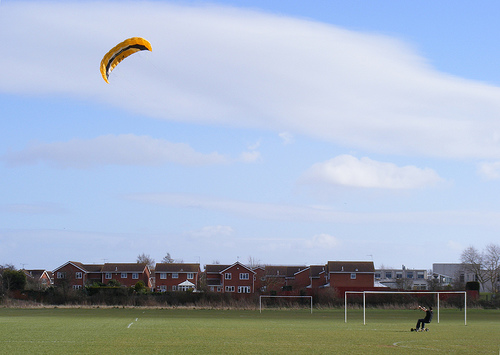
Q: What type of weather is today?
A: It is cloudy.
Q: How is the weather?
A: It is cloudy.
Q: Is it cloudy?
A: Yes, it is cloudy.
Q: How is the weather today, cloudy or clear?
A: It is cloudy.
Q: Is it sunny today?
A: No, it is cloudy.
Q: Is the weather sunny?
A: No, it is cloudy.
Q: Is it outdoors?
A: Yes, it is outdoors.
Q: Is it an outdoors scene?
A: Yes, it is outdoors.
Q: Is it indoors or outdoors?
A: It is outdoors.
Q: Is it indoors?
A: No, it is outdoors.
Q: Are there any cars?
A: No, there are no cars.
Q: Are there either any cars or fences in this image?
A: No, there are no cars or fences.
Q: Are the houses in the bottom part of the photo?
A: Yes, the houses are in the bottom of the image.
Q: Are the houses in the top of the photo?
A: No, the houses are in the bottom of the image.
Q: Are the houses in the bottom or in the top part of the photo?
A: The houses are in the bottom of the image.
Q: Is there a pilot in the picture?
A: No, there are no pilots.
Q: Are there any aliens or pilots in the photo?
A: No, there are no pilots or aliens.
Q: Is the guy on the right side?
A: Yes, the guy is on the right of the image.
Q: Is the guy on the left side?
A: No, the guy is on the right of the image.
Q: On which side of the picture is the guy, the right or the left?
A: The guy is on the right of the image.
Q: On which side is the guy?
A: The guy is on the right of the image.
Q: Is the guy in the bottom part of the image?
A: Yes, the guy is in the bottom of the image.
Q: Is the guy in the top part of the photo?
A: No, the guy is in the bottom of the image.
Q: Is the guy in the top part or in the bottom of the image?
A: The guy is in the bottom of the image.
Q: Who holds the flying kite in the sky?
A: The guy holds the kite.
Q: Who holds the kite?
A: The guy holds the kite.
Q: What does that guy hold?
A: The guy holds the kite.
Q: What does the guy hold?
A: The guy holds the kite.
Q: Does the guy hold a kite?
A: Yes, the guy holds a kite.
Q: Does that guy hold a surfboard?
A: No, the guy holds a kite.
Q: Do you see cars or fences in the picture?
A: No, there are no fences or cars.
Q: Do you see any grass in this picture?
A: Yes, there is grass.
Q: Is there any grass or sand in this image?
A: Yes, there is grass.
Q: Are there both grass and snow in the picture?
A: No, there is grass but no snow.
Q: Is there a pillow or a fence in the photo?
A: No, there are no fences or pillows.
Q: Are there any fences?
A: No, there are no fences.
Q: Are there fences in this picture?
A: No, there are no fences.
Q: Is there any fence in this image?
A: No, there are no fences.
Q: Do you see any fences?
A: No, there are no fences.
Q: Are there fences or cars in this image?
A: No, there are no fences or cars.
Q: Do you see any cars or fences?
A: No, there are no fences or cars.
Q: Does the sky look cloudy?
A: Yes, the sky is cloudy.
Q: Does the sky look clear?
A: No, the sky is cloudy.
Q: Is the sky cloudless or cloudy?
A: The sky is cloudy.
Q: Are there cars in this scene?
A: No, there are no cars.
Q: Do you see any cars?
A: No, there are no cars.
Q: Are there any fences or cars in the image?
A: No, there are no cars or fences.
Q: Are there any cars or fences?
A: No, there are no cars or fences.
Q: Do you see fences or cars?
A: No, there are no cars or fences.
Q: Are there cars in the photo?
A: No, there are no cars.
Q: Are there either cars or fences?
A: No, there are no cars or fences.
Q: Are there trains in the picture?
A: No, there are no trains.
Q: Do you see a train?
A: No, there are no trains.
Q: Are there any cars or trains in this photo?
A: No, there are no trains or cars.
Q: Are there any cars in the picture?
A: No, there are no cars.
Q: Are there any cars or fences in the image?
A: No, there are no cars or fences.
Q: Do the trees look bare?
A: Yes, the trees are bare.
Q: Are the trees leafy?
A: No, the trees are bare.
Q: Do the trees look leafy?
A: No, the trees are bare.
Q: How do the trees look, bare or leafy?
A: The trees are bare.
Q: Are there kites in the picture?
A: Yes, there is a kite.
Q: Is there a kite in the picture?
A: Yes, there is a kite.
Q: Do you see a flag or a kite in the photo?
A: Yes, there is a kite.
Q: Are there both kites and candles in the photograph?
A: No, there is a kite but no candles.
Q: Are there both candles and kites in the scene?
A: No, there is a kite but no candles.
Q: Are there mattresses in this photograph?
A: No, there are no mattresses.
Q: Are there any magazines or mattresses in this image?
A: No, there are no mattresses or magazines.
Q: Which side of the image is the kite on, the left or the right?
A: The kite is on the left of the image.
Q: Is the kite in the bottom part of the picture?
A: No, the kite is in the top of the image.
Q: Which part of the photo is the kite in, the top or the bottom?
A: The kite is in the top of the image.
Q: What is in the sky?
A: The kite is in the sky.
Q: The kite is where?
A: The kite is in the sky.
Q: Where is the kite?
A: The kite is in the sky.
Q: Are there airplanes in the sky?
A: No, there is a kite in the sky.